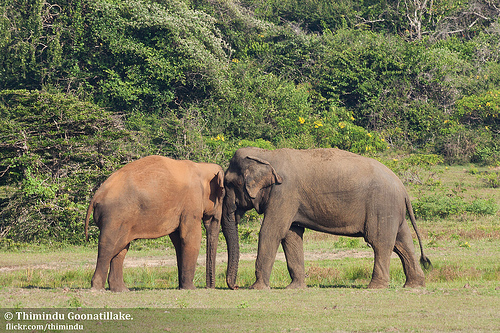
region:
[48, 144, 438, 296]
two elephants playing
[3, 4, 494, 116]
a dense forest in the background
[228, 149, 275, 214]
the head of one elephant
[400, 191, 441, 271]
the elephant long tail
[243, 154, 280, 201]
one large ear of the elephant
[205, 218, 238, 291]
two long elephants' trunks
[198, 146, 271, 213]
two elephant heads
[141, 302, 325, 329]
some grass in the field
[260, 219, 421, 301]
four elephant legs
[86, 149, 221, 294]
looks like a baby elephant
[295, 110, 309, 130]
Yellow flower on the trees.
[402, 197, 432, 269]
Tail of an elephant.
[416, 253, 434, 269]
Small group of hair on elephant.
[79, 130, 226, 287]
Brownish elephant on the left.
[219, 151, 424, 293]
Big grey elephant on the right.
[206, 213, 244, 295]
Two elephant trunks close to each other.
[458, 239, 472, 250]
Small yellow flowers on the ground.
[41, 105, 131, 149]
Brown sticks in the mountains.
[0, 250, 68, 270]
Small trail made of dirt.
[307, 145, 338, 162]
Big spot on the back of elephant.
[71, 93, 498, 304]
Elephants on the ground.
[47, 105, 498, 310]
Elephants in the wild.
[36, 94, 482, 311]
Brown and gray elephant.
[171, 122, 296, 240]
Elephants touching heads.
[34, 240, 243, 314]
Grass on the ground.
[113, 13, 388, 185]
Trees and bushes in the background.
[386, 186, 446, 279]
Tail of the elephant.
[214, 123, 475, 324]
Big grey elephant.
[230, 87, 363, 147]
Yellow flowers on the trees.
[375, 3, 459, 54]
Branches on the tree.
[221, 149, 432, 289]
Larger and darker elephant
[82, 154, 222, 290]
Smaller red tinted elephant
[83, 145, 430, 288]
Elephants touching their heads together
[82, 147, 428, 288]
Two elephants standing together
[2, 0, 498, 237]
Forested area with lots of plants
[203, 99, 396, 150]
Bush with yellow flowers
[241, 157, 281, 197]
An elephant's large ear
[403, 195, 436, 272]
An elephant's tail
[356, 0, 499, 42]
A dead brown tree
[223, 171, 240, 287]
An elephant's long trunk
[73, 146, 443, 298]
Two elephants are bumping heads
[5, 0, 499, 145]
A mountain covered in vegetation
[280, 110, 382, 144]
Yellow flowers adorn that bush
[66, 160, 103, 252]
That is an elephants tail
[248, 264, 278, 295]
That is an elephants foot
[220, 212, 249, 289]
This is an elephants trunk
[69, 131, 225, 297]
This is a young brown elephant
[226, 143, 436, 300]
This is an older dark brown elephant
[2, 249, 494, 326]
That is the well trampled ground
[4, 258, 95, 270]
This is part of the dirt road